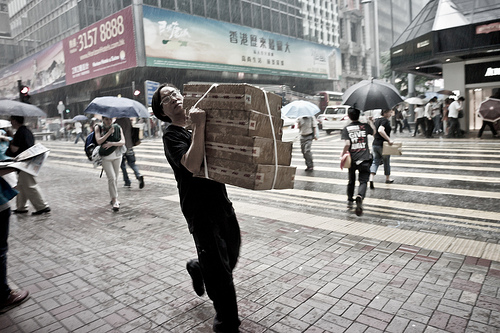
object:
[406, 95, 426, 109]
umbrella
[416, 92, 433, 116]
hand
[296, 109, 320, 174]
man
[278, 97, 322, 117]
umbrella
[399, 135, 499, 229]
white lines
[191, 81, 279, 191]
string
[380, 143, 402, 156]
boxes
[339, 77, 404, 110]
black umbrella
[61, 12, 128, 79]
large banner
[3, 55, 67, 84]
large banner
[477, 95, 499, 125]
umbrella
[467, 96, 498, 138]
person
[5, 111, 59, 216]
person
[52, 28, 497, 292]
people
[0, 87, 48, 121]
umbrella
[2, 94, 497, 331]
street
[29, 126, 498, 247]
road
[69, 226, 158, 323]
sidewalk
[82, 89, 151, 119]
umbrella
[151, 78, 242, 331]
person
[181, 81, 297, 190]
boxes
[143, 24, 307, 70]
ads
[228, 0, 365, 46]
building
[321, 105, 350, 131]
car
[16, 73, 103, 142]
sign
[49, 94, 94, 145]
pole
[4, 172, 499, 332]
brick sidewalk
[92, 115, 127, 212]
lady